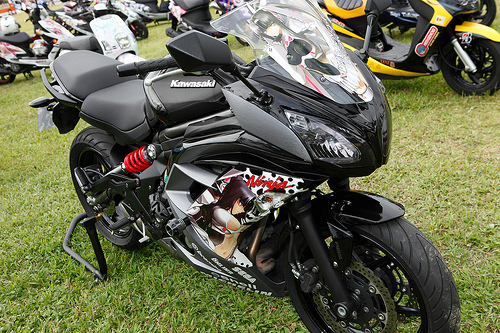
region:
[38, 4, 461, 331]
a black red and gray Kawasaki motorcycle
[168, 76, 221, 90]
silver metal Kawasaki motorcycle nameplate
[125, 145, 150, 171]
red metal spring coil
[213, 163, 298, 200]
black white and red Ninja logo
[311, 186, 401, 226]
shiny black wheel fender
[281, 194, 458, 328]
wide rubber wheel tire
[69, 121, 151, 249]
wide rubber wheel tire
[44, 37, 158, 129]
white black two seater bike seat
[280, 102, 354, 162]
pointed motorcycle headlight off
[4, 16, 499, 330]
green cut grass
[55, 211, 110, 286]
Support/stand near the rear tire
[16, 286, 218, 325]
Green grassy ground surface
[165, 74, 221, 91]
'Kawasaki' on the motorcycle in the foreground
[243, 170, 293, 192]
Red 'Ninja' on the motorcycle in the foreground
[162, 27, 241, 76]
Rear view mirror on the motorcycle in the foreground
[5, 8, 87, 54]
Cluster of motorcycles in the top left corner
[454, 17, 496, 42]
Yellow portion of the yellow motorcycle over the front tire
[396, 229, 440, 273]
Front tire of the motorcycle in the foreground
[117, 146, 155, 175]
Red rings on the motorcycle in the foreground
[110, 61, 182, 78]
Handlebar on the motorcycle in the foreground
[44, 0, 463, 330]
the bike is new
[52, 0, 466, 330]
the bike is black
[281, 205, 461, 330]
the tire is black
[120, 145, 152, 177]
the coil is red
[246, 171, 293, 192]
the words are red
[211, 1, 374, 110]
the shield is clear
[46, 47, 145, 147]
the sits are gray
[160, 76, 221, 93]
the word is silver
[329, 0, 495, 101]
the bike is yellow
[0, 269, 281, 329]
the grass is green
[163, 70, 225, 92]
the motorcycle is a kawasaki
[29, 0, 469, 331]
the motorcycle is black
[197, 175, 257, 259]
the motorcycle has a girl painted on the side of it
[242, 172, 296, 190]
the motorcycles has the word ninja on the side of it above the painting of the girl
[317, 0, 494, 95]
the scooter to the right and behind the motorcycle in the front is yellow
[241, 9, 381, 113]
the motorcycle has a girl painted on the windshield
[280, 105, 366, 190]
the motorcycles right headlight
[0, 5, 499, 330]
the grass is very green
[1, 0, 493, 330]
there are many motorcycles and scooters parked in this picture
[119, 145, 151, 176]
the shock on the side of the motorcycle is red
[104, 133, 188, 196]
Red motorcycle part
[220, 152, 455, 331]
Front wheel of a motorcycle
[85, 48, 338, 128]
Handle bar of a motorcycle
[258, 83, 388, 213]
Light on a motorcycle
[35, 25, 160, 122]
Seat on a motorcycle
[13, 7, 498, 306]
black motorcycle sitting in grass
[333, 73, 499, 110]
Grass under a motorcycle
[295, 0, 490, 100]
Yellow and black motorcycle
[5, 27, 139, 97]
Red and white motorcycle sitting on grass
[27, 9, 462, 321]
Red, black and silver motorcycle